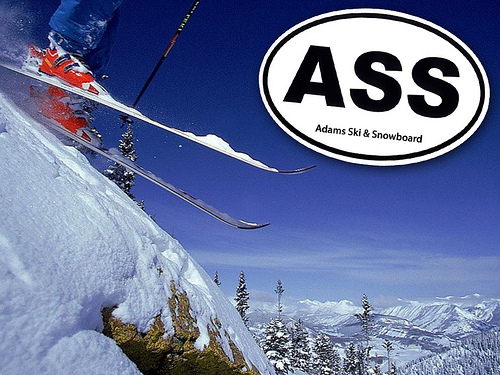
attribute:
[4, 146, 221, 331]
mountain — white, snowy, beautiful, steep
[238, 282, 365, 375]
trees — brown, distance, tall, thin, green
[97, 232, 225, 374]
hill — snowy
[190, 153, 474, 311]
sky — blue, beautiful, clear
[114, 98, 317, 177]
ski — long, snowy, upward, mid air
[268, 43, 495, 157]
sign — white, black, oval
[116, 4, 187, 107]
ski stick — black, brown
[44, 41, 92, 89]
sneaker — red, black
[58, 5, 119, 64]
pants — blue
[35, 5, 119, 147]
man — skiing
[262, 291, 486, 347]
mountains — distance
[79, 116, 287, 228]
skis — gray, thin, long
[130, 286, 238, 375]
rock — brown, exposed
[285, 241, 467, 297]
cloud — white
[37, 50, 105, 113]
boots — red, orange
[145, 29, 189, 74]
ski pole — black, red, thin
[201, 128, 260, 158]
snow — small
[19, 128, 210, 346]
slope — steep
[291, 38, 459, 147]
logo — black, white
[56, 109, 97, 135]
shoe — red